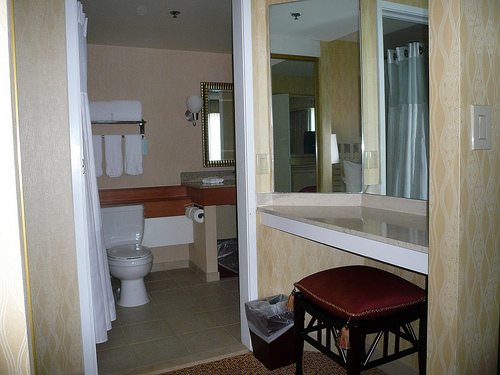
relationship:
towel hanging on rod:
[102, 133, 123, 180] [100, 133, 145, 138]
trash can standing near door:
[242, 292, 299, 372] [74, 0, 99, 371]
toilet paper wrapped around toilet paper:
[190, 206, 205, 224] [188, 206, 205, 224]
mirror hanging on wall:
[267, 1, 365, 193] [252, 1, 367, 352]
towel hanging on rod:
[90, 131, 105, 177] [100, 132, 145, 138]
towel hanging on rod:
[102, 133, 124, 179] [100, 131, 145, 137]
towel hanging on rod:
[122, 131, 144, 176] [100, 132, 145, 138]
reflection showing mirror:
[269, 50, 320, 192] [269, 51, 322, 191]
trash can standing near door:
[242, 292, 299, 372] [66, 1, 101, 372]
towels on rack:
[89, 97, 144, 119] [90, 118, 147, 140]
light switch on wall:
[467, 105, 493, 153] [425, 0, 499, 370]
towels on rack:
[86, 99, 143, 124] [90, 118, 147, 140]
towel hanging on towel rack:
[102, 133, 124, 179] [87, 132, 145, 142]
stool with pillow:
[291, 293, 424, 372] [301, 262, 425, 313]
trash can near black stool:
[243, 288, 303, 369] [291, 262, 428, 372]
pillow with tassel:
[285, 264, 427, 349] [334, 312, 353, 353]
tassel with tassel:
[334, 312, 353, 353] [277, 279, 299, 319]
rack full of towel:
[90, 105, 150, 145] [120, 130, 146, 175]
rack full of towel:
[90, 105, 150, 145] [106, 132, 120, 173]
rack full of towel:
[90, 105, 150, 145] [91, 132, 106, 179]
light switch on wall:
[468, 96, 485, 157] [424, 3, 484, 373]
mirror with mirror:
[191, 76, 238, 174] [198, 80, 236, 168]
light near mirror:
[182, 88, 203, 128] [197, 77, 237, 169]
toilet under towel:
[96, 204, 153, 309] [122, 128, 145, 178]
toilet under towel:
[96, 204, 153, 309] [102, 135, 124, 179]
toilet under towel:
[96, 204, 153, 309] [93, 133, 104, 182]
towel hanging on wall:
[122, 131, 144, 176] [85, 40, 241, 274]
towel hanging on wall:
[102, 133, 124, 179] [85, 40, 241, 274]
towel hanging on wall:
[90, 132, 105, 178] [85, 40, 241, 274]